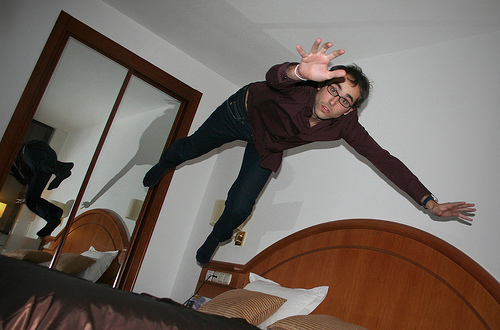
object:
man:
[142, 38, 477, 265]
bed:
[0, 219, 499, 329]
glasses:
[326, 84, 354, 109]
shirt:
[247, 61, 431, 205]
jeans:
[157, 82, 273, 242]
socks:
[195, 238, 218, 266]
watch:
[419, 194, 437, 209]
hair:
[328, 63, 371, 110]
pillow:
[198, 289, 288, 326]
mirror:
[0, 36, 182, 288]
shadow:
[80, 94, 182, 209]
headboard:
[193, 218, 499, 329]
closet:
[1, 8, 204, 293]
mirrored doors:
[4, 37, 181, 287]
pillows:
[267, 313, 368, 330]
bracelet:
[294, 63, 308, 83]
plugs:
[205, 269, 215, 281]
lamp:
[209, 199, 227, 226]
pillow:
[242, 270, 330, 329]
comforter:
[0, 254, 264, 329]